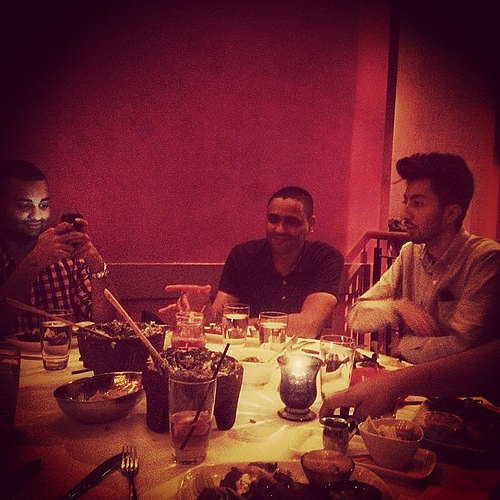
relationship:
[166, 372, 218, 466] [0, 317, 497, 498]
glass on table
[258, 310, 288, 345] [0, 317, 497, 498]
glass on table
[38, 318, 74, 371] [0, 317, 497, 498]
glass on table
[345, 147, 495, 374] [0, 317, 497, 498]
man at table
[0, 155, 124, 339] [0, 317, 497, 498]
friends at table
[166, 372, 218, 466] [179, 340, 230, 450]
glass with straw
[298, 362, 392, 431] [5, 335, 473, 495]
hand on table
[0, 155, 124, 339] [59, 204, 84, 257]
friends looking at phone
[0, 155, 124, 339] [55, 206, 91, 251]
friends holding phone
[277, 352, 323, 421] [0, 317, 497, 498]
candle on table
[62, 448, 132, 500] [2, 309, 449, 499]
fork on table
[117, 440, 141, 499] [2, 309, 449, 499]
fork on table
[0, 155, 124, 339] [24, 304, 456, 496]
friends seated around table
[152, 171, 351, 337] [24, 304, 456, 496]
gentlement seated around table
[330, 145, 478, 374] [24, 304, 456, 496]
gentlement seated around table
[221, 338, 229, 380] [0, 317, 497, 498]
straw on table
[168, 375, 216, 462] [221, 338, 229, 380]
glass with straw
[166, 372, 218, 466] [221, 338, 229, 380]
glass with straw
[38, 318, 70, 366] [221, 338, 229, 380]
glass with straw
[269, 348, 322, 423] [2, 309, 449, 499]
ambiance on table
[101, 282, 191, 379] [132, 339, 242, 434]
spoon in food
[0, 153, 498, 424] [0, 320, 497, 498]
friends eating meal